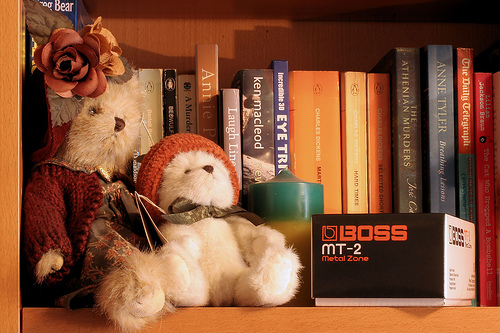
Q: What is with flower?
A: Bear.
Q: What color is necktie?
A: Green.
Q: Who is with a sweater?
A: Momma bear.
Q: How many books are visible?
A: Fifteen.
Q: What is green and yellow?
A: Candle.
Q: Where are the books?
A: Shelf.